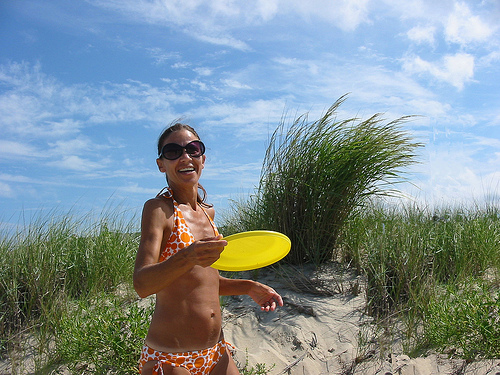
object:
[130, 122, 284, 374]
woman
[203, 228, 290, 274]
frisbee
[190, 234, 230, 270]
hand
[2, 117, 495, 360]
grass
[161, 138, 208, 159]
sunglasses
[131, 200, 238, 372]
swimsuit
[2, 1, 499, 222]
sky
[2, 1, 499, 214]
clouds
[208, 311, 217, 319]
belly button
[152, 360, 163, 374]
tie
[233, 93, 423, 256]
bush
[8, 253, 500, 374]
sand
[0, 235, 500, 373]
beach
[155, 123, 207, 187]
head